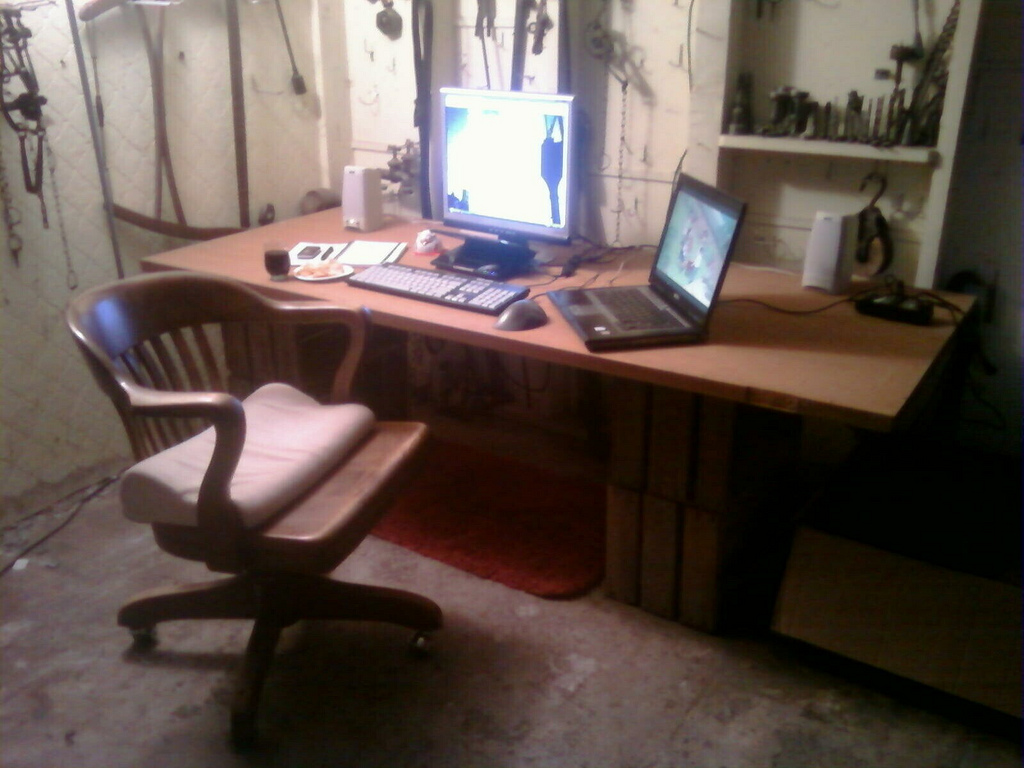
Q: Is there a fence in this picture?
A: No, there are no fences.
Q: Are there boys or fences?
A: No, there are no fences or boys.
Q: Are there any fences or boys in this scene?
A: No, there are no fences or boys.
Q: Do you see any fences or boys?
A: No, there are no fences or boys.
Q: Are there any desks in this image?
A: Yes, there is a desk.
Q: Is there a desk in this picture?
A: Yes, there is a desk.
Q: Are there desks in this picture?
A: Yes, there is a desk.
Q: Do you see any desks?
A: Yes, there is a desk.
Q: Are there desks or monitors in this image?
A: Yes, there is a desk.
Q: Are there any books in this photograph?
A: No, there are no books.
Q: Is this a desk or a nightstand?
A: This is a desk.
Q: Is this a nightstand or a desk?
A: This is a desk.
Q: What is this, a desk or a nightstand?
A: This is a desk.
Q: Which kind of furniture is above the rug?
A: The piece of furniture is a desk.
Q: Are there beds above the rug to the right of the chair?
A: No, there is a desk above the rug.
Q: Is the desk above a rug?
A: Yes, the desk is above a rug.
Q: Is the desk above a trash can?
A: No, the desk is above a rug.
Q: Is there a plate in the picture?
A: Yes, there is a plate.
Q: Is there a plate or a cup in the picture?
A: Yes, there is a plate.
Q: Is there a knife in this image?
A: No, there are no knives.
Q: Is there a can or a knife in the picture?
A: No, there are no knives or cans.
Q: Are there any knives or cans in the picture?
A: No, there are no knives or cans.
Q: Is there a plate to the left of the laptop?
A: Yes, there is a plate to the left of the laptop.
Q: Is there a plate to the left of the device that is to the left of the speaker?
A: Yes, there is a plate to the left of the laptop.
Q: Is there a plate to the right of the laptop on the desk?
A: No, the plate is to the left of the laptop.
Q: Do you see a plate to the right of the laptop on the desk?
A: No, the plate is to the left of the laptop.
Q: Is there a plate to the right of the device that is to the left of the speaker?
A: No, the plate is to the left of the laptop.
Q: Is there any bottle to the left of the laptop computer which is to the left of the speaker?
A: No, there is a plate to the left of the laptop.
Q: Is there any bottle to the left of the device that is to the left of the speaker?
A: No, there is a plate to the left of the laptop.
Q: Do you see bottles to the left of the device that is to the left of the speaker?
A: No, there is a plate to the left of the laptop.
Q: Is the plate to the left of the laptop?
A: Yes, the plate is to the left of the laptop.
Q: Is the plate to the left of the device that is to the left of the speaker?
A: Yes, the plate is to the left of the laptop.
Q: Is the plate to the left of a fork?
A: No, the plate is to the left of the laptop.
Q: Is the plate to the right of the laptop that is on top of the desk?
A: No, the plate is to the left of the laptop computer.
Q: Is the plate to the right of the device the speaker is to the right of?
A: No, the plate is to the left of the laptop computer.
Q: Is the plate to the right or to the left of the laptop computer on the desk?
A: The plate is to the left of the laptop.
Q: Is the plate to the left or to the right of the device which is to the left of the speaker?
A: The plate is to the left of the laptop.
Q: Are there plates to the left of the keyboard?
A: Yes, there is a plate to the left of the keyboard.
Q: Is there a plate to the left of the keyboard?
A: Yes, there is a plate to the left of the keyboard.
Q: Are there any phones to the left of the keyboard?
A: No, there is a plate to the left of the keyboard.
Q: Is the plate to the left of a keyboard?
A: Yes, the plate is to the left of a keyboard.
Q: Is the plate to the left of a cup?
A: No, the plate is to the left of a keyboard.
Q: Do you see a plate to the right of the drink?
A: Yes, there is a plate to the right of the drink.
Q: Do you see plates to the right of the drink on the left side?
A: Yes, there is a plate to the right of the drink.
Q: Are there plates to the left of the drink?
A: No, the plate is to the right of the drink.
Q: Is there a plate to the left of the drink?
A: No, the plate is to the right of the drink.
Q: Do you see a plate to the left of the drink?
A: No, the plate is to the right of the drink.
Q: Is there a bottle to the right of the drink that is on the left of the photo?
A: No, there is a plate to the right of the drink.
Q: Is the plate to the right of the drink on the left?
A: Yes, the plate is to the right of the drink.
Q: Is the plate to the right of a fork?
A: No, the plate is to the right of the drink.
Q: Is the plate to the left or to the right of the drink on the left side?
A: The plate is to the right of the drink.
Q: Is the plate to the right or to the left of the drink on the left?
A: The plate is to the right of the drink.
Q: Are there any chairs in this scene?
A: Yes, there is a chair.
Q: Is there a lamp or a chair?
A: Yes, there is a chair.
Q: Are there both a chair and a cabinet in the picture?
A: No, there is a chair but no cabinets.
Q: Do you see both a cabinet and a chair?
A: No, there is a chair but no cabinets.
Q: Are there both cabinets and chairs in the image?
A: No, there is a chair but no cabinets.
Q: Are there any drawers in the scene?
A: No, there are no drawers.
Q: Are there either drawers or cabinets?
A: No, there are no drawers or cabinets.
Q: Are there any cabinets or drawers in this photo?
A: No, there are no drawers or cabinets.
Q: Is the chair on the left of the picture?
A: Yes, the chair is on the left of the image.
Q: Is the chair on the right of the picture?
A: No, the chair is on the left of the image.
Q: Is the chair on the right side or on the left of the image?
A: The chair is on the left of the image.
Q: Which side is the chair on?
A: The chair is on the left of the image.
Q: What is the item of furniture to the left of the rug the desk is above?
A: The piece of furniture is a chair.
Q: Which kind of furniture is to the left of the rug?
A: The piece of furniture is a chair.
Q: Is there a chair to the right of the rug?
A: No, the chair is to the left of the rug.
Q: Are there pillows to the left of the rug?
A: No, there is a chair to the left of the rug.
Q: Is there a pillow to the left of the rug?
A: No, there is a chair to the left of the rug.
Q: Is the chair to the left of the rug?
A: Yes, the chair is to the left of the rug.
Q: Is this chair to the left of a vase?
A: No, the chair is to the left of the rug.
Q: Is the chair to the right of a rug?
A: No, the chair is to the left of a rug.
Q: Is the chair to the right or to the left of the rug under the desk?
A: The chair is to the left of the rug.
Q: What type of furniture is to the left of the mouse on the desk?
A: The piece of furniture is a chair.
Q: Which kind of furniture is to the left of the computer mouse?
A: The piece of furniture is a chair.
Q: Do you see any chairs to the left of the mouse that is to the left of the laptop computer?
A: Yes, there is a chair to the left of the mouse.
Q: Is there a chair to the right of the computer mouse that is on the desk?
A: No, the chair is to the left of the computer mouse.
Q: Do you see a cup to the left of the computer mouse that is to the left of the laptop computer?
A: No, there is a chair to the left of the computer mouse.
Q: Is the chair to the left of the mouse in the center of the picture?
A: Yes, the chair is to the left of the mouse.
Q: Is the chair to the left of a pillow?
A: No, the chair is to the left of the mouse.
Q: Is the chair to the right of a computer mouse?
A: No, the chair is to the left of a computer mouse.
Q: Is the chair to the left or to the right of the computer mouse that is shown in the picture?
A: The chair is to the left of the computer mouse.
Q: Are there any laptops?
A: Yes, there is a laptop.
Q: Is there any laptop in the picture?
A: Yes, there is a laptop.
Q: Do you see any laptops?
A: Yes, there is a laptop.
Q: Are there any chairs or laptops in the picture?
A: Yes, there is a laptop.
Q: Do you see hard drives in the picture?
A: No, there are no hard drives.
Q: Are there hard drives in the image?
A: No, there are no hard drives.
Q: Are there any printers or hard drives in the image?
A: No, there are no hard drives or printers.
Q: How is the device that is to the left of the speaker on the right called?
A: The device is a laptop.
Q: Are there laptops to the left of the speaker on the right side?
A: Yes, there is a laptop to the left of the speaker.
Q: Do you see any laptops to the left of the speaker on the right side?
A: Yes, there is a laptop to the left of the speaker.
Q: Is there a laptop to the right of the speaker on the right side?
A: No, the laptop is to the left of the speaker.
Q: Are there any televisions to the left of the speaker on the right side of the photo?
A: No, there is a laptop to the left of the speaker.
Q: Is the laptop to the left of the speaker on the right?
A: Yes, the laptop is to the left of the speaker.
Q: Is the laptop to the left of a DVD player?
A: No, the laptop is to the left of the speaker.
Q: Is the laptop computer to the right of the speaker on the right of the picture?
A: No, the laptop computer is to the left of the speaker.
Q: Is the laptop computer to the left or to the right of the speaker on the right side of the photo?
A: The laptop computer is to the left of the speaker.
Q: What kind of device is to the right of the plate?
A: The device is a laptop.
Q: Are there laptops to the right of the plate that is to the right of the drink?
A: Yes, there is a laptop to the right of the plate.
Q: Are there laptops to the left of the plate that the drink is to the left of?
A: No, the laptop is to the right of the plate.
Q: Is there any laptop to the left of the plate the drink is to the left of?
A: No, the laptop is to the right of the plate.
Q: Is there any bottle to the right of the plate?
A: No, there is a laptop to the right of the plate.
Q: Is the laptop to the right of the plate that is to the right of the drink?
A: Yes, the laptop is to the right of the plate.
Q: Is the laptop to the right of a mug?
A: No, the laptop is to the right of the plate.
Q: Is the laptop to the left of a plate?
A: No, the laptop is to the right of a plate.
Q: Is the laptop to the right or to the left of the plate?
A: The laptop is to the right of the plate.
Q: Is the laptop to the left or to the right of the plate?
A: The laptop is to the right of the plate.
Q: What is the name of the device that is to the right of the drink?
A: The device is a laptop.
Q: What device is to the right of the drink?
A: The device is a laptop.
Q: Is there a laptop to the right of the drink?
A: Yes, there is a laptop to the right of the drink.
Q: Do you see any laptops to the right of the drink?
A: Yes, there is a laptop to the right of the drink.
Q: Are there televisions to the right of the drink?
A: No, there is a laptop to the right of the drink.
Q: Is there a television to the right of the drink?
A: No, there is a laptop to the right of the drink.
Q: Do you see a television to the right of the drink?
A: No, there is a laptop to the right of the drink.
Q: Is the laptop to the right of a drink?
A: Yes, the laptop is to the right of a drink.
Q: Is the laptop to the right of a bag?
A: No, the laptop is to the right of a drink.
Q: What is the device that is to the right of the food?
A: The device is a laptop.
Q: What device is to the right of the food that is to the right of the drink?
A: The device is a laptop.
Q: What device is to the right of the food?
A: The device is a laptop.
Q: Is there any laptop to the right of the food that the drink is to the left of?
A: Yes, there is a laptop to the right of the food.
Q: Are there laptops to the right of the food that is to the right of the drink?
A: Yes, there is a laptop to the right of the food.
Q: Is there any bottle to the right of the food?
A: No, there is a laptop to the right of the food.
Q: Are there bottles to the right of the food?
A: No, there is a laptop to the right of the food.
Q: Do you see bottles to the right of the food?
A: No, there is a laptop to the right of the food.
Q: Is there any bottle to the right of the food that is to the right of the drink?
A: No, there is a laptop to the right of the food.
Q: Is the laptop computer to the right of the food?
A: Yes, the laptop computer is to the right of the food.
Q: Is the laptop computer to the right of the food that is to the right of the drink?
A: Yes, the laptop computer is to the right of the food.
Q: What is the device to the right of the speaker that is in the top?
A: The device is a laptop.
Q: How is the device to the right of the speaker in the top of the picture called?
A: The device is a laptop.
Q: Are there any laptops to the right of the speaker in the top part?
A: Yes, there is a laptop to the right of the speaker.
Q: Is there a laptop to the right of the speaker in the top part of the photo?
A: Yes, there is a laptop to the right of the speaker.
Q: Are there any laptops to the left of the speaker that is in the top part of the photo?
A: No, the laptop is to the right of the speaker.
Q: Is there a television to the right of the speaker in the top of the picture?
A: No, there is a laptop to the right of the speaker.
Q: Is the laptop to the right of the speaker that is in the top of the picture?
A: Yes, the laptop is to the right of the speaker.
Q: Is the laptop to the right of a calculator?
A: No, the laptop is to the right of the speaker.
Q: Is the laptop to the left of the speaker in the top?
A: No, the laptop is to the right of the speaker.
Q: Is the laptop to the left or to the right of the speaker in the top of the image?
A: The laptop is to the right of the speaker.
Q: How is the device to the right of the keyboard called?
A: The device is a laptop.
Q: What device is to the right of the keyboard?
A: The device is a laptop.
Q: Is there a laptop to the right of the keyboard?
A: Yes, there is a laptop to the right of the keyboard.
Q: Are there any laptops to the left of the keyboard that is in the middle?
A: No, the laptop is to the right of the keyboard.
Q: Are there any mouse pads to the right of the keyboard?
A: No, there is a laptop to the right of the keyboard.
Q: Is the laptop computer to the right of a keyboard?
A: Yes, the laptop computer is to the right of a keyboard.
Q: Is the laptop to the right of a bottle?
A: No, the laptop is to the right of a keyboard.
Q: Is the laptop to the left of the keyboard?
A: No, the laptop is to the right of the keyboard.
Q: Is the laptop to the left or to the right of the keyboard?
A: The laptop is to the right of the keyboard.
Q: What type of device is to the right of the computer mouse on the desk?
A: The device is a laptop.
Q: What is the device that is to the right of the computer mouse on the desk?
A: The device is a laptop.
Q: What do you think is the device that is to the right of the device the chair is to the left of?
A: The device is a laptop.